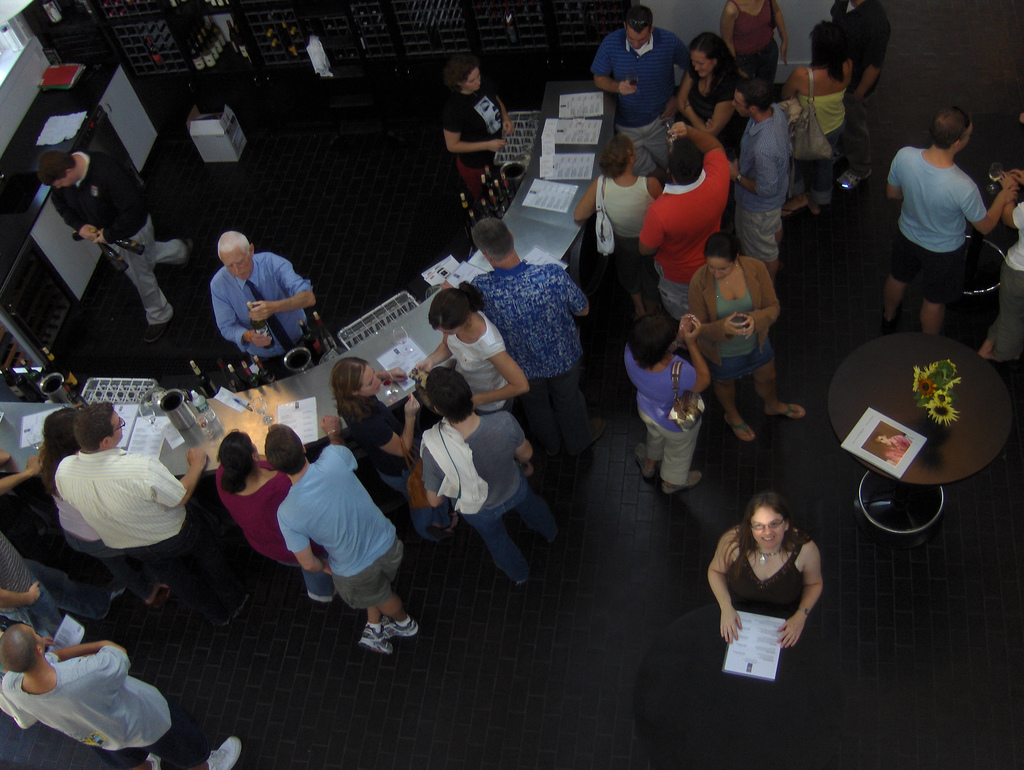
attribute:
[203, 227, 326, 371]
man — older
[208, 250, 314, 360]
shirt — blue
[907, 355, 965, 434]
sunflowers — yellow, orange, centerpiece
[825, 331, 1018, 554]
table — black, round, small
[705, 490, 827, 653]
woman — wearing brown, looking up, smiling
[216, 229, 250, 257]
hair — white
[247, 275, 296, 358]
tie — black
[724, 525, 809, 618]
tank top — brown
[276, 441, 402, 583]
top — light blue, blue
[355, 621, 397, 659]
sneaker — white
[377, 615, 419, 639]
sneaker — white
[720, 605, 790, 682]
menu — white, paper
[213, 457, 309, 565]
shirt — pink, purple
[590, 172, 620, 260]
purse — white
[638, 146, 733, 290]
shirt — red-orange, red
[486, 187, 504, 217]
bottle — unopen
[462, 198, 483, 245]
bottle — unopen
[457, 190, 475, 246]
bottle — unopen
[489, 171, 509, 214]
bottle — unopen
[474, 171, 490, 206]
bottle — unopen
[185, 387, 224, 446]
water bottle — plastic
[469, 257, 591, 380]
shirt — blue, white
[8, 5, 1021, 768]
floor — tiled, brick paved, black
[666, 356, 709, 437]
purse — beige, large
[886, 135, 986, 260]
shirt — light blue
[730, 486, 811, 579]
hair — brown